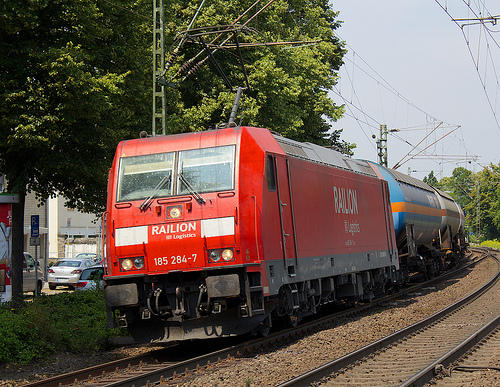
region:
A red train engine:
[87, 126, 405, 319]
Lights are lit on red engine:
[101, 229, 251, 281]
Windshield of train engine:
[115, 144, 243, 201]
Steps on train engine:
[283, 253, 304, 317]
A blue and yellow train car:
[371, 163, 446, 230]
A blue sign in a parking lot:
[25, 211, 42, 239]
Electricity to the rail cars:
[154, 7, 453, 132]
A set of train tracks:
[391, 324, 460, 374]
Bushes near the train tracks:
[6, 304, 91, 384]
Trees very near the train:
[36, 27, 143, 172]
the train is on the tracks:
[95, 123, 409, 350]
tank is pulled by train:
[348, 155, 475, 279]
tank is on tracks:
[350, 154, 471, 272]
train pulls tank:
[94, 127, 469, 342]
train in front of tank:
[100, 120, 471, 341]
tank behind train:
[92, 121, 476, 345]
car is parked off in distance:
[41, 245, 103, 293]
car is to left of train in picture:
[42, 248, 104, 298]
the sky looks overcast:
[310, 3, 498, 188]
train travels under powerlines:
[107, 0, 498, 348]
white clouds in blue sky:
[337, 19, 390, 56]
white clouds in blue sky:
[339, 51, 385, 74]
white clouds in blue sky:
[355, 67, 412, 111]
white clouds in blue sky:
[421, 126, 469, 142]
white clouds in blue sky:
[392, 49, 463, 113]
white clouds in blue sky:
[369, 19, 469, 74]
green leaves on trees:
[44, 45, 217, 112]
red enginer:
[108, 124, 270, 291]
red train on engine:
[128, 131, 336, 266]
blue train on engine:
[380, 154, 483, 230]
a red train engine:
[103, 130, 402, 345]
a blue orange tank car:
[364, 155, 440, 282]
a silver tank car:
[433, 183, 464, 270]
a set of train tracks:
[30, 341, 235, 383]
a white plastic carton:
[275, 237, 499, 384]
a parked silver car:
[46, 254, 91, 284]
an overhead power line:
[432, 0, 499, 130]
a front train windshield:
[117, 145, 236, 198]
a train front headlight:
[119, 258, 132, 271]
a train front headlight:
[220, 245, 231, 259]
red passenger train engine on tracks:
[91, 132, 388, 303]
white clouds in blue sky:
[337, 2, 445, 60]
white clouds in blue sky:
[410, 23, 454, 68]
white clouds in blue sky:
[347, 35, 412, 79]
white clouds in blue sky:
[352, 82, 423, 109]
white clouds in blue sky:
[415, 117, 470, 152]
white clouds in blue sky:
[442, 70, 495, 121]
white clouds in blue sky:
[379, 66, 452, 108]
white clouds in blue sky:
[416, 2, 496, 96]